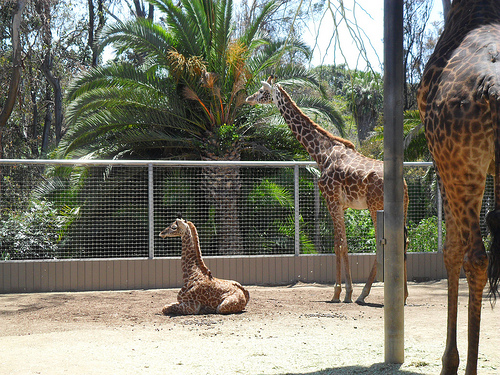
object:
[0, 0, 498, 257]
tree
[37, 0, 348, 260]
palm tree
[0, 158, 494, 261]
fence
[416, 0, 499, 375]
giraffe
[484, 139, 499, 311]
tail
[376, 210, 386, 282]
box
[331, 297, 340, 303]
hoof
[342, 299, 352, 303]
hoof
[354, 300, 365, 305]
hoof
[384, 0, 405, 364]
pole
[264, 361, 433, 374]
shadow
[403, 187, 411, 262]
tail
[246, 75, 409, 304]
giraffe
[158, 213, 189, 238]
head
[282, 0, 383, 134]
branches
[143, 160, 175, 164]
silver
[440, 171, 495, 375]
leg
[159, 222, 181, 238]
face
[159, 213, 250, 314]
giraffe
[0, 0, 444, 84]
sky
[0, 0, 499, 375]
zoo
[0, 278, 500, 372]
ground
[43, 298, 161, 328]
sand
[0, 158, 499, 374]
area